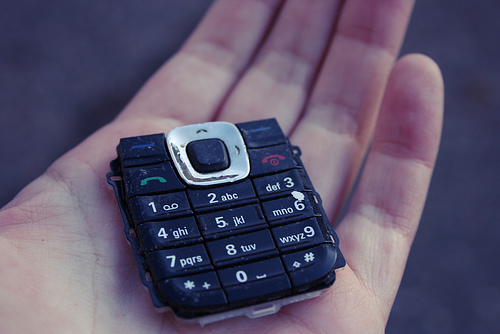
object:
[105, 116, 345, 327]
keypad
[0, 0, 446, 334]
hand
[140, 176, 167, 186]
phone handset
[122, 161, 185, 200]
button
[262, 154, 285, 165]
phone handset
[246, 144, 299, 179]
button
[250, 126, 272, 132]
line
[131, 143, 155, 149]
line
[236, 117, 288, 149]
button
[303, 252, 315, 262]
number sign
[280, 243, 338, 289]
button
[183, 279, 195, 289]
asterisk sign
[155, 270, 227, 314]
button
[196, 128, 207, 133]
arrow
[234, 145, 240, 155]
arrow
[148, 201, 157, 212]
one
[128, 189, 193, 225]
button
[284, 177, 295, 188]
three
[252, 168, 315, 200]
button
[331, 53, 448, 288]
pinky finger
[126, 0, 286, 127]
index finger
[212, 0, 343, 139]
middle finger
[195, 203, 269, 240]
buttons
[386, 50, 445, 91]
finger tip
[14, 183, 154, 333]
palm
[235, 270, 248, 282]
zero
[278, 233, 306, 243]
wxyz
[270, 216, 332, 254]
button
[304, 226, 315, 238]
nine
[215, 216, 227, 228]
five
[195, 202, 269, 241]
button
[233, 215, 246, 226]
jkl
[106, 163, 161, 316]
metal flange